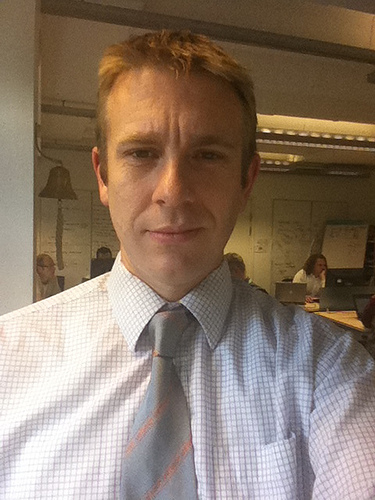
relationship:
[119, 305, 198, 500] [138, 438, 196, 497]
necktie with stripe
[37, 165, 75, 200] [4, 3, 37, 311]
bell hanging on wall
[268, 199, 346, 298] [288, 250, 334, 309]
white board behind woman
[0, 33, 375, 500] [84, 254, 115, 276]
man behind computer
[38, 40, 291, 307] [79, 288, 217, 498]
man wearing tie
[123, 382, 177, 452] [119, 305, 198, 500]
stripe on necktie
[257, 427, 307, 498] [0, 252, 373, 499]
pocket on dress shirt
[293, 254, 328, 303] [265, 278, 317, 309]
man on computer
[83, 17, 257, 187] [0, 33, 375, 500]
blonde hair on man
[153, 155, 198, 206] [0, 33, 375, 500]
nose on man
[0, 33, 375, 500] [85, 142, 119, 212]
man has ear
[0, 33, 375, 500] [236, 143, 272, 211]
man has ear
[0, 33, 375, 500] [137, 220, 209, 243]
man has mouth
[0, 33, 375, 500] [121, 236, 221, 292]
man has chin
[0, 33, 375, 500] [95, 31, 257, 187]
man has blonde hair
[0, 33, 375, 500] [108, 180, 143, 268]
man has cheek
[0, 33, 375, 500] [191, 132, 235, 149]
man has eyebrow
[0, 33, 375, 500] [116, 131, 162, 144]
man has eyebrow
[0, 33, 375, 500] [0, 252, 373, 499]
man wearing dress shirt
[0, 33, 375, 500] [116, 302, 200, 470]
man wearing necktie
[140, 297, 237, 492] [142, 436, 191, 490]
necktie has stripe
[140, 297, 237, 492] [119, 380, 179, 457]
necktie has stripe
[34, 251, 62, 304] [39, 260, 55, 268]
man wearing glasses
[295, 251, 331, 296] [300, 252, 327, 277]
man has hair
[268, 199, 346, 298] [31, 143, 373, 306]
white board on wall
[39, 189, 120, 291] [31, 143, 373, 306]
white board on wall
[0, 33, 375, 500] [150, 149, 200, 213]
man has nose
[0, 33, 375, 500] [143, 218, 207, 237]
man has mouth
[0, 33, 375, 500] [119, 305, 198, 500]
man has necktie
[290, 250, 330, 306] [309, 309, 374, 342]
woman at desk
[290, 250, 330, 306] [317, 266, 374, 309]
woman by computer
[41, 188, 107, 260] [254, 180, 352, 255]
writing on a whiteboard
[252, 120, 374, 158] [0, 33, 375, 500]
lights behind man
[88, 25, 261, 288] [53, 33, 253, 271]
head of man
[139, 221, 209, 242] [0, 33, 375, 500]
lips of man